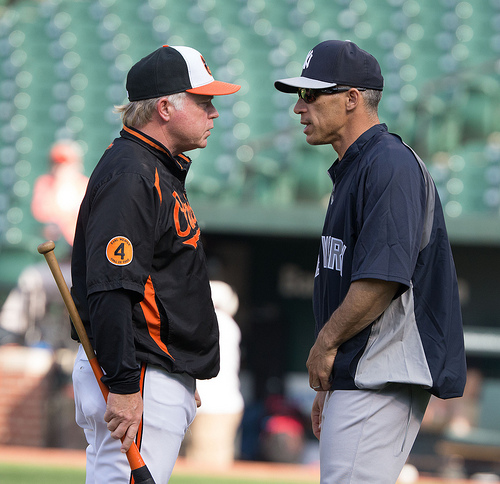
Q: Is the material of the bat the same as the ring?
A: No, the bat is made of wood and the ring is made of metal.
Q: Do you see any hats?
A: Yes, there is a hat.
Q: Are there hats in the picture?
A: Yes, there is a hat.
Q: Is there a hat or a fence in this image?
A: Yes, there is a hat.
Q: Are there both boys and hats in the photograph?
A: No, there is a hat but no boys.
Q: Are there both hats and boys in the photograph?
A: No, there is a hat but no boys.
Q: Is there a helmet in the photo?
A: No, there are no helmets.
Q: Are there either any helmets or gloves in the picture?
A: No, there are no helmets or gloves.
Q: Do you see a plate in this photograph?
A: No, there are no plates.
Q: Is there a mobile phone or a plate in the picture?
A: No, there are no plates or cell phones.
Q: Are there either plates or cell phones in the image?
A: No, there are no plates or cell phones.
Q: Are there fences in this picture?
A: No, there are no fences.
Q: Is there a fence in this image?
A: No, there are no fences.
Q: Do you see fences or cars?
A: No, there are no fences or cars.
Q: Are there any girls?
A: No, there are no girls.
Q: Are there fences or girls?
A: No, there are no girls or fences.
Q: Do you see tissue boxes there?
A: No, there are no tissue boxes.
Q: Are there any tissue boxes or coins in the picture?
A: No, there are no tissue boxes or coins.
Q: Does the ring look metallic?
A: Yes, the ring is metallic.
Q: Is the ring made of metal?
A: Yes, the ring is made of metal.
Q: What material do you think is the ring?
A: The ring is made of metal.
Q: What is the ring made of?
A: The ring is made of metal.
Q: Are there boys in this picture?
A: No, there are no boys.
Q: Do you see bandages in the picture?
A: No, there are no bandages.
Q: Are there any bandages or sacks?
A: No, there are no bandages or sacks.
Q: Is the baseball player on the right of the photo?
A: Yes, the player is on the right of the image.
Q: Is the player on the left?
A: No, the player is on the right of the image.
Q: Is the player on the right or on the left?
A: The player is on the right of the image.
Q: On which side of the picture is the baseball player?
A: The player is on the right of the image.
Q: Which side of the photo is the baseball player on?
A: The player is on the right of the image.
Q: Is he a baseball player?
A: Yes, this is a baseball player.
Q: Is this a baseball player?
A: Yes, this is a baseball player.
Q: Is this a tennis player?
A: No, this is a baseball player.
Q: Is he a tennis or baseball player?
A: This is a baseball player.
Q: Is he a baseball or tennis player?
A: This is a baseball player.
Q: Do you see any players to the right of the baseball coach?
A: Yes, there is a player to the right of the coach.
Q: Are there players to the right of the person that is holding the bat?
A: Yes, there is a player to the right of the coach.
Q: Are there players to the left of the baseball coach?
A: No, the player is to the right of the coach.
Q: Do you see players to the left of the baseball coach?
A: No, the player is to the right of the coach.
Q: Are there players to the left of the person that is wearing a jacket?
A: No, the player is to the right of the coach.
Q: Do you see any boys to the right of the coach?
A: No, there is a player to the right of the coach.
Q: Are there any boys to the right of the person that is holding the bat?
A: No, there is a player to the right of the coach.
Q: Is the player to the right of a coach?
A: Yes, the player is to the right of a coach.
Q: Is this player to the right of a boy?
A: No, the player is to the right of a coach.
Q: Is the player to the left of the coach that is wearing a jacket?
A: No, the player is to the right of the coach.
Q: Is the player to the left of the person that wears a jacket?
A: No, the player is to the right of the coach.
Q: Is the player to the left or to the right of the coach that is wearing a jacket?
A: The player is to the right of the coach.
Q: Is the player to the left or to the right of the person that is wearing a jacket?
A: The player is to the right of the coach.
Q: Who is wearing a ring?
A: The player is wearing a ring.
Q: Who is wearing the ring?
A: The player is wearing a ring.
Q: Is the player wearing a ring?
A: Yes, the player is wearing a ring.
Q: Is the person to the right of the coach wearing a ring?
A: Yes, the player is wearing a ring.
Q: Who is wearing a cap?
A: The player is wearing a cap.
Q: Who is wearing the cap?
A: The player is wearing a cap.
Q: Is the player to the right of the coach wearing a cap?
A: Yes, the player is wearing a cap.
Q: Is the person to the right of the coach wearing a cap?
A: Yes, the player is wearing a cap.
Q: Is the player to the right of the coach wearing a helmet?
A: No, the player is wearing a cap.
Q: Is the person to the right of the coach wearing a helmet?
A: No, the player is wearing a cap.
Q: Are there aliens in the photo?
A: No, there are no aliens.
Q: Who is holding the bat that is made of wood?
A: The coach is holding the bat.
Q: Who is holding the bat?
A: The coach is holding the bat.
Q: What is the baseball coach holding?
A: The coach is holding the bat.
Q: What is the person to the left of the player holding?
A: The coach is holding the bat.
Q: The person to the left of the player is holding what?
A: The coach is holding the bat.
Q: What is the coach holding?
A: The coach is holding the bat.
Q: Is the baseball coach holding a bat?
A: Yes, the coach is holding a bat.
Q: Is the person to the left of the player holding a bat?
A: Yes, the coach is holding a bat.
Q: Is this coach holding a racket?
A: No, the coach is holding a bat.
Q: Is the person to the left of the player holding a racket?
A: No, the coach is holding a bat.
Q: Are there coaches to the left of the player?
A: Yes, there is a coach to the left of the player.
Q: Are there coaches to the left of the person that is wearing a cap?
A: Yes, there is a coach to the left of the player.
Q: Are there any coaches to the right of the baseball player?
A: No, the coach is to the left of the player.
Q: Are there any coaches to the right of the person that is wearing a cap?
A: No, the coach is to the left of the player.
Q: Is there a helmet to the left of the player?
A: No, there is a coach to the left of the player.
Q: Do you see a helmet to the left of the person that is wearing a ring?
A: No, there is a coach to the left of the player.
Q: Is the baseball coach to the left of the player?
A: Yes, the coach is to the left of the player.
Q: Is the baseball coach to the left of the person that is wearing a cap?
A: Yes, the coach is to the left of the player.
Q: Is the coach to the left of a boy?
A: No, the coach is to the left of the player.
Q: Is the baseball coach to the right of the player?
A: No, the coach is to the left of the player.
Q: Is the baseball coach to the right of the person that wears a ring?
A: No, the coach is to the left of the player.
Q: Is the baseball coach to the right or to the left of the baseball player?
A: The coach is to the left of the player.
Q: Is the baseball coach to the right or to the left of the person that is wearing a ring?
A: The coach is to the left of the player.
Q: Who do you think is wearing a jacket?
A: The coach is wearing a jacket.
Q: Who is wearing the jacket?
A: The coach is wearing a jacket.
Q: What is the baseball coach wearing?
A: The coach is wearing a jacket.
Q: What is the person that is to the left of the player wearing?
A: The coach is wearing a jacket.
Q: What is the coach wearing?
A: The coach is wearing a jacket.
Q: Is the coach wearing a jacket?
A: Yes, the coach is wearing a jacket.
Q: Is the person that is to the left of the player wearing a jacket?
A: Yes, the coach is wearing a jacket.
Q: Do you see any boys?
A: No, there are no boys.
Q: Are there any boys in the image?
A: No, there are no boys.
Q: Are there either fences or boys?
A: No, there are no boys or fences.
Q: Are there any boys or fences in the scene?
A: No, there are no boys or fences.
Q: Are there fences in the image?
A: No, there are no fences.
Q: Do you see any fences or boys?
A: No, there are no fences or boys.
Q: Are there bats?
A: Yes, there is a bat.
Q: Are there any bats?
A: Yes, there is a bat.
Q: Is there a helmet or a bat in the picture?
A: Yes, there is a bat.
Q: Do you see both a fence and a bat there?
A: No, there is a bat but no fences.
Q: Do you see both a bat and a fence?
A: No, there is a bat but no fences.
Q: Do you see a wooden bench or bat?
A: Yes, there is a wood bat.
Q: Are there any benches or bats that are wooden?
A: Yes, the bat is wooden.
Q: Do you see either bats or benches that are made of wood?
A: Yes, the bat is made of wood.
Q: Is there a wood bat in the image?
A: Yes, there is a wood bat.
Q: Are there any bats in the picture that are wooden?
A: Yes, there is a bat that is wooden.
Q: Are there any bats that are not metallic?
A: Yes, there is a wooden bat.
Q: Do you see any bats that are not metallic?
A: Yes, there is a wooden bat.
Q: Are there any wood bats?
A: Yes, there is a bat that is made of wood.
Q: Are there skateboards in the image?
A: No, there are no skateboards.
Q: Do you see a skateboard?
A: No, there are no skateboards.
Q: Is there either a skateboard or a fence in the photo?
A: No, there are no skateboards or fences.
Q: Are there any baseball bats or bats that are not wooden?
A: No, there is a bat but it is wooden.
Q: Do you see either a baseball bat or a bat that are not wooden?
A: No, there is a bat but it is wooden.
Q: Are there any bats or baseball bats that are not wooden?
A: No, there is a bat but it is wooden.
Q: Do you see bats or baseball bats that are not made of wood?
A: No, there is a bat but it is made of wood.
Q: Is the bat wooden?
A: Yes, the bat is wooden.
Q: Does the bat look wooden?
A: Yes, the bat is wooden.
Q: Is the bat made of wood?
A: Yes, the bat is made of wood.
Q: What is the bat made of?
A: The bat is made of wood.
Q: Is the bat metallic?
A: No, the bat is wooden.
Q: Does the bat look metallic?
A: No, the bat is wooden.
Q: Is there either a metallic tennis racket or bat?
A: No, there is a bat but it is wooden.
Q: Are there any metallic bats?
A: No, there is a bat but it is wooden.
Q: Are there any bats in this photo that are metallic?
A: No, there is a bat but it is wooden.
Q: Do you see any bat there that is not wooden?
A: No, there is a bat but it is wooden.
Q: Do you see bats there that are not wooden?
A: No, there is a bat but it is wooden.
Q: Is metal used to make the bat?
A: No, the bat is made of wood.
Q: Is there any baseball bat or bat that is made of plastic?
A: No, there is a bat but it is made of wood.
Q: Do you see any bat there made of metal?
A: No, there is a bat but it is made of wood.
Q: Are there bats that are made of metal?
A: No, there is a bat but it is made of wood.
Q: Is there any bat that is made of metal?
A: No, there is a bat but it is made of wood.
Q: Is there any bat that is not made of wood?
A: No, there is a bat but it is made of wood.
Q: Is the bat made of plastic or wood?
A: The bat is made of wood.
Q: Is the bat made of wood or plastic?
A: The bat is made of wood.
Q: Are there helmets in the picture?
A: No, there are no helmets.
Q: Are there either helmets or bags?
A: No, there are no helmets or bags.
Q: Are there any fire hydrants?
A: No, there are no fire hydrants.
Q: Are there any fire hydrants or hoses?
A: No, there are no fire hydrants or hoses.